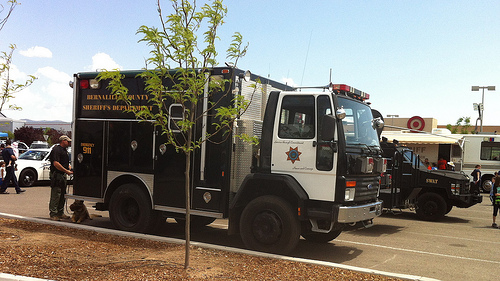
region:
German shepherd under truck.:
[67, 198, 102, 225]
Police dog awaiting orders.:
[70, 202, 102, 224]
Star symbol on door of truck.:
[281, 145, 302, 165]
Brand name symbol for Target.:
[402, 115, 424, 133]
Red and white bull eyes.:
[407, 117, 424, 134]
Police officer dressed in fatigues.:
[49, 136, 72, 221]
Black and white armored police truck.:
[61, 66, 383, 256]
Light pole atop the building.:
[471, 84, 494, 125]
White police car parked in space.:
[0, 147, 53, 187]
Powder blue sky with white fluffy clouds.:
[36, 6, 136, 66]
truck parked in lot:
[60, 61, 389, 253]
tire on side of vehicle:
[235, 182, 302, 243]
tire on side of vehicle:
[101, 178, 158, 239]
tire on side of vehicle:
[408, 185, 453, 229]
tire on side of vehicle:
[24, 165, 39, 185]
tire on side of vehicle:
[307, 228, 342, 243]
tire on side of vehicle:
[176, 213, 203, 231]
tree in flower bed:
[128, 25, 210, 275]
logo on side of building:
[405, 115, 422, 131]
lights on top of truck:
[311, 80, 371, 107]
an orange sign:
[82, 88, 161, 120]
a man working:
[41, 130, 81, 223]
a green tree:
[144, 14, 234, 270]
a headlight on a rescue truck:
[341, 187, 358, 207]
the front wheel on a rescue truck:
[225, 198, 309, 252]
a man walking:
[1, 137, 29, 203]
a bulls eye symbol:
[401, 113, 430, 136]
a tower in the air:
[470, 72, 494, 132]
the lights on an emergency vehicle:
[329, 80, 379, 103]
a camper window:
[467, 127, 498, 156]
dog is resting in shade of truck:
[66, 198, 92, 225]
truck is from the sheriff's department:
[78, 101, 157, 116]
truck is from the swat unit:
[423, 175, 441, 186]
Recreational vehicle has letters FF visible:
[382, 129, 498, 191]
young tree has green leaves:
[106, 0, 264, 275]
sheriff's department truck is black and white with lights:
[68, 68, 395, 255]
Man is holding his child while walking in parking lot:
[2, 138, 27, 199]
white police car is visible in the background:
[2, 140, 77, 190]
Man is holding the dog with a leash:
[47, 131, 97, 225]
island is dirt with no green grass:
[0, 211, 409, 279]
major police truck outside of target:
[67, 66, 380, 253]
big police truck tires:
[230, 195, 300, 250]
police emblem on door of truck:
[282, 144, 307, 166]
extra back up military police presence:
[378, 138, 481, 214]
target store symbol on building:
[404, 116, 428, 131]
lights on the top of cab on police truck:
[330, 82, 372, 102]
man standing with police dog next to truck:
[45, 131, 95, 222]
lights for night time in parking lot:
[471, 85, 495, 133]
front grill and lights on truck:
[342, 178, 379, 203]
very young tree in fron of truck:
[97, 1, 259, 269]